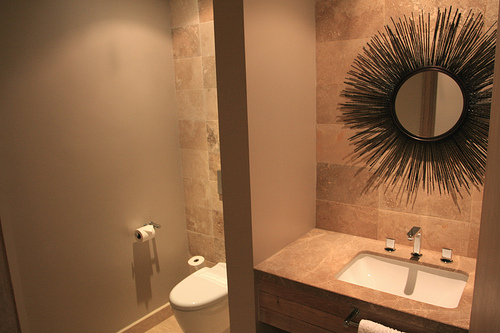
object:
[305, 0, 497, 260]
wall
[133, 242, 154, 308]
shadow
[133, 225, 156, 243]
tp roll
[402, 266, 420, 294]
shadow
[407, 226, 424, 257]
faucet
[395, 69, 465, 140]
mirror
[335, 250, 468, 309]
sink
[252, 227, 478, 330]
counter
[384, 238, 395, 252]
hot water knob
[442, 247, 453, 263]
cold water knob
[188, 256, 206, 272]
toilet paper roll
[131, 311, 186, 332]
ground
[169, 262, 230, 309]
lid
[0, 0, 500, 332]
toilet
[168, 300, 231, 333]
bowl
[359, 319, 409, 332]
towel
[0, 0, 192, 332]
wall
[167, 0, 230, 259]
tile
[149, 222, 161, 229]
holder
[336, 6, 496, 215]
frame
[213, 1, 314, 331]
support wall